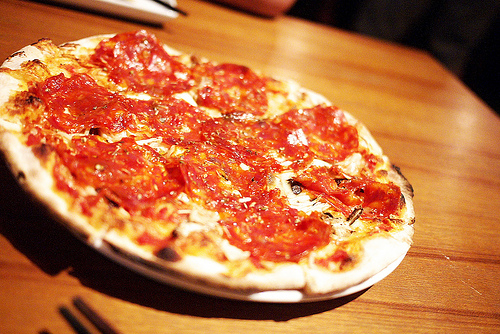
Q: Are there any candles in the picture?
A: No, there are no candles.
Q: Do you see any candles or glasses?
A: No, there are no candles or glasses.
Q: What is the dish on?
A: The dish is on the table.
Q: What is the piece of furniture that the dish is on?
A: The piece of furniture is a table.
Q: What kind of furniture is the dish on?
A: The dish is on the table.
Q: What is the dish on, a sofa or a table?
A: The dish is on a table.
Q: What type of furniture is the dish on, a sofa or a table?
A: The dish is on a table.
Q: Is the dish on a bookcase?
A: No, the dish is on the table.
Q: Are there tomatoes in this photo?
A: Yes, there is a tomato.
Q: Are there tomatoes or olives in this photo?
A: Yes, there is a tomato.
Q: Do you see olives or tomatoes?
A: Yes, there is a tomato.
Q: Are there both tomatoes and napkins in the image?
A: No, there is a tomato but no napkins.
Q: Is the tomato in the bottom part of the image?
A: Yes, the tomato is in the bottom of the image.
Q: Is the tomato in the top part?
A: No, the tomato is in the bottom of the image.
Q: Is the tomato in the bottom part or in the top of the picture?
A: The tomato is in the bottom of the image.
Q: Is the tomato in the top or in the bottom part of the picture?
A: The tomato is in the bottom of the image.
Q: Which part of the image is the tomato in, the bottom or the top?
A: The tomato is in the bottom of the image.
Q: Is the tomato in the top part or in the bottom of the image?
A: The tomato is in the bottom of the image.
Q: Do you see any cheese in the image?
A: Yes, there is cheese.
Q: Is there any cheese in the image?
A: Yes, there is cheese.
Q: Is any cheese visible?
A: Yes, there is cheese.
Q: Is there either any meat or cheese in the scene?
A: Yes, there is cheese.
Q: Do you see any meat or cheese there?
A: Yes, there is cheese.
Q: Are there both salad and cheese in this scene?
A: No, there is cheese but no salad.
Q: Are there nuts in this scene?
A: No, there are no nuts.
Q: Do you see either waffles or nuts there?
A: No, there are no nuts or waffles.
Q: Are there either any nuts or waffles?
A: No, there are no nuts or waffles.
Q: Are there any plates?
A: Yes, there is a plate.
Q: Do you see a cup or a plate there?
A: Yes, there is a plate.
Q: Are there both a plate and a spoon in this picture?
A: No, there is a plate but no spoons.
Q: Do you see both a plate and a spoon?
A: No, there is a plate but no spoons.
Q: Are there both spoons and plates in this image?
A: No, there is a plate but no spoons.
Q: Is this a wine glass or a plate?
A: This is a plate.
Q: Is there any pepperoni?
A: Yes, there is pepperoni.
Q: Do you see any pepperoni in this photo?
A: Yes, there is pepperoni.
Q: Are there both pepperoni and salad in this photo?
A: No, there is pepperoni but no salad.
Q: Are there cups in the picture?
A: No, there are no cups.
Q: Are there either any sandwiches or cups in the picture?
A: No, there are no cups or sandwiches.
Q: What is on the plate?
A: The pepperoni is on the plate.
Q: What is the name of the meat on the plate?
A: The meat is pepperoni.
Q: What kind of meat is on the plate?
A: The meat is pepperoni.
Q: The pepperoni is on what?
A: The pepperoni is on the plate.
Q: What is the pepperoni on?
A: The pepperoni is on the plate.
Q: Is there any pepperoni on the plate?
A: Yes, there is pepperoni on the plate.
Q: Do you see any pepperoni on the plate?
A: Yes, there is pepperoni on the plate.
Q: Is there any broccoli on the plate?
A: No, there is pepperoni on the plate.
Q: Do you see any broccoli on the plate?
A: No, there is pepperoni on the plate.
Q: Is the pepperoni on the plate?
A: Yes, the pepperoni is on the plate.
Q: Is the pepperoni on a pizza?
A: No, the pepperoni is on the plate.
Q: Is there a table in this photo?
A: Yes, there is a table.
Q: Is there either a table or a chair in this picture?
A: Yes, there is a table.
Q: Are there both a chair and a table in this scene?
A: No, there is a table but no chairs.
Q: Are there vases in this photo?
A: No, there are no vases.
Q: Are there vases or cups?
A: No, there are no vases or cups.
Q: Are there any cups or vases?
A: No, there are no vases or cups.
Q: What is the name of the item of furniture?
A: The piece of furniture is a table.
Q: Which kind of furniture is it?
A: The piece of furniture is a table.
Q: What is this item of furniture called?
A: This is a table.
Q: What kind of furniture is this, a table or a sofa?
A: This is a table.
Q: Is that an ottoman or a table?
A: That is a table.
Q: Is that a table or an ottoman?
A: That is a table.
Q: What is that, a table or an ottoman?
A: That is a table.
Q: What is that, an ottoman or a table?
A: That is a table.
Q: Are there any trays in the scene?
A: No, there are no trays.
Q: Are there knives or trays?
A: No, there are no trays or knives.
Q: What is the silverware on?
A: The silverware is on the table.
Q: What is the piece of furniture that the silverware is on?
A: The piece of furniture is a table.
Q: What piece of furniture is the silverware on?
A: The silverware is on the table.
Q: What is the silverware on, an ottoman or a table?
A: The silverware is on a table.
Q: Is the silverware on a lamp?
A: No, the silverware is on the table.